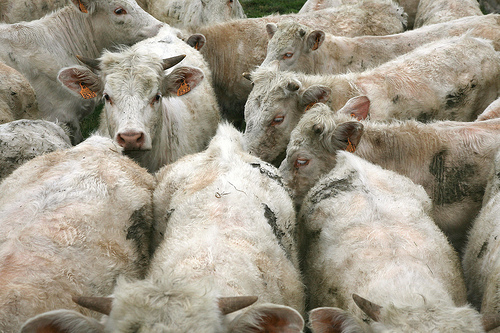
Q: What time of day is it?
A: Daytime.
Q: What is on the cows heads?
A: Horns.